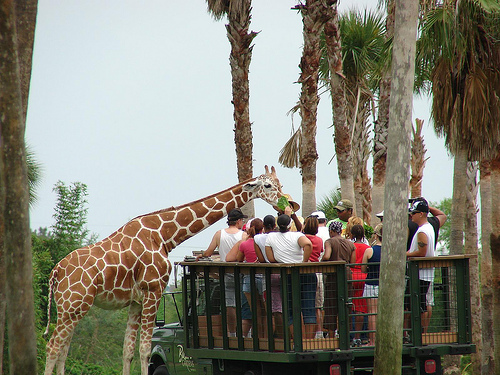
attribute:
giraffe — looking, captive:
[43, 163, 293, 374]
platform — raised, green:
[186, 335, 479, 360]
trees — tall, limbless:
[204, 2, 500, 373]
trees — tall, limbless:
[0, 2, 39, 374]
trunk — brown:
[6, 183, 39, 375]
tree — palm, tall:
[308, 5, 396, 235]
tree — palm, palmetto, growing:
[420, 2, 492, 253]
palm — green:
[304, 7, 394, 92]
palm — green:
[416, 2, 500, 100]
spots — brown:
[69, 248, 164, 300]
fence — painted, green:
[297, 260, 470, 350]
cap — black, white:
[408, 198, 432, 217]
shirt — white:
[265, 231, 311, 264]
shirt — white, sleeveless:
[216, 226, 245, 261]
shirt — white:
[253, 230, 274, 263]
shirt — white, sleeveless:
[410, 224, 440, 283]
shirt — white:
[312, 226, 335, 260]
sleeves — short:
[264, 232, 307, 247]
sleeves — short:
[417, 229, 431, 239]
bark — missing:
[387, 159, 405, 271]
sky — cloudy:
[29, 0, 459, 280]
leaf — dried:
[281, 100, 302, 170]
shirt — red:
[305, 235, 325, 263]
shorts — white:
[220, 268, 251, 312]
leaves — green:
[59, 186, 86, 238]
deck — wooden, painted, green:
[176, 266, 477, 363]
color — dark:
[412, 199, 430, 213]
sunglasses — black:
[411, 209, 423, 216]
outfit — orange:
[348, 242, 374, 312]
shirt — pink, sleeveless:
[239, 235, 262, 267]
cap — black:
[226, 206, 250, 222]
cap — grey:
[333, 198, 355, 213]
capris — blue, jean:
[281, 266, 320, 326]